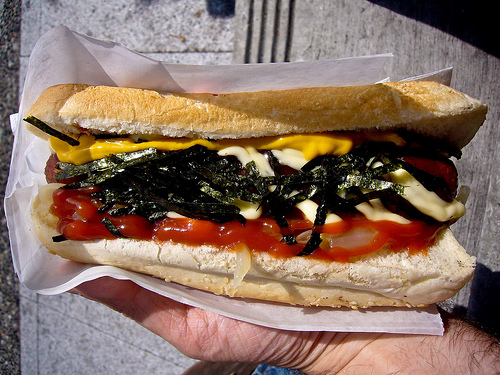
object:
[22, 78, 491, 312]
sandwich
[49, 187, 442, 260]
ketchup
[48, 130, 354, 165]
mustard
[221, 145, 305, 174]
bead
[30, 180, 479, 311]
bottom bread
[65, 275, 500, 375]
human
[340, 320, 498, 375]
arm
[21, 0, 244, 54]
brick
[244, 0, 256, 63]
lines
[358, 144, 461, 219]
hot dog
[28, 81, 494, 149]
bun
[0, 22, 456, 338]
wrapper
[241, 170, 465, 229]
topping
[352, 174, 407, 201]
mayo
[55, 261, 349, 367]
hand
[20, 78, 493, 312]
bread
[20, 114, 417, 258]
seaweed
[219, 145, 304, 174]
cheese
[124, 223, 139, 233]
peppers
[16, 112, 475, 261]
filling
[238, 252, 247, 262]
onions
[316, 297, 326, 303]
sesame seeds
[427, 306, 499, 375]
hair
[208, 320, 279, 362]
wrinkles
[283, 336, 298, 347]
wrinkles